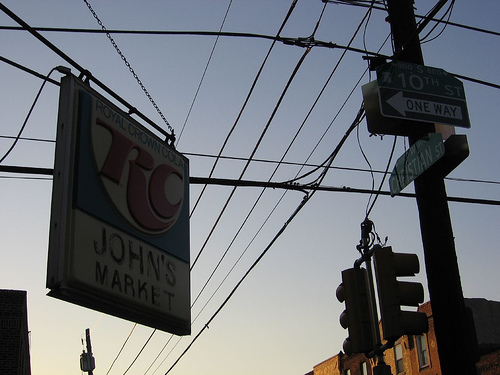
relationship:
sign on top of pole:
[47, 84, 212, 330] [401, 185, 496, 340]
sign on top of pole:
[368, 59, 484, 141] [401, 185, 496, 340]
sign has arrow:
[368, 59, 484, 141] [386, 86, 458, 121]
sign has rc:
[47, 84, 212, 330] [75, 97, 189, 237]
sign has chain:
[47, 84, 212, 330] [114, 37, 142, 86]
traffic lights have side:
[326, 229, 423, 368] [347, 275, 377, 353]